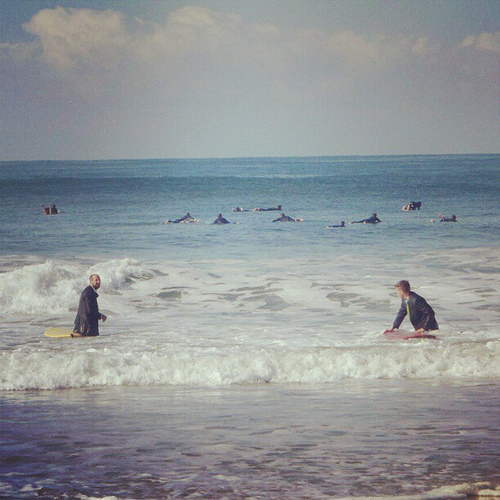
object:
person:
[381, 277, 438, 337]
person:
[69, 274, 109, 338]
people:
[33, 195, 467, 231]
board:
[376, 325, 442, 345]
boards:
[42, 206, 452, 234]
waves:
[1, 245, 494, 392]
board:
[33, 321, 113, 343]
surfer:
[74, 272, 113, 342]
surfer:
[383, 273, 444, 332]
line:
[4, 154, 230, 166]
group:
[170, 209, 381, 238]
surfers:
[37, 197, 467, 231]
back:
[3, 159, 498, 268]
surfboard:
[381, 329, 437, 345]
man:
[75, 270, 105, 340]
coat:
[72, 292, 98, 328]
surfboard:
[43, 325, 76, 342]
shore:
[15, 460, 306, 497]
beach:
[4, 467, 286, 497]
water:
[0, 180, 500, 498]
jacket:
[400, 299, 430, 320]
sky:
[1, 0, 497, 156]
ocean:
[0, 161, 494, 497]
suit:
[71, 289, 101, 339]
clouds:
[0, 13, 488, 101]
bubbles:
[271, 282, 312, 309]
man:
[385, 275, 433, 338]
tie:
[386, 294, 424, 336]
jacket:
[72, 279, 106, 336]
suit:
[392, 297, 436, 331]